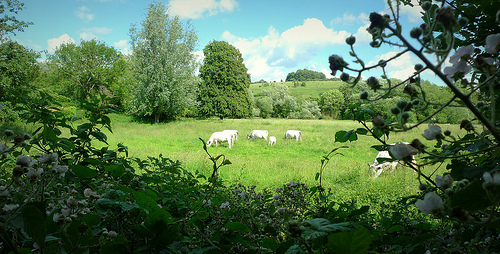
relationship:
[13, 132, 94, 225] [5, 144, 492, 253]
flowers in foreground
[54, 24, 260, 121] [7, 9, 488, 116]
trees in background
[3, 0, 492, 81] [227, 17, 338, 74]
sky has clouds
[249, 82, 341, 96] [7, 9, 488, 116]
meadow in background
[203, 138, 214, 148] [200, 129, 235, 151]
head of cow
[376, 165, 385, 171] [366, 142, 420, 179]
ear of cow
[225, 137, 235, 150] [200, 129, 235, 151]
legs of cow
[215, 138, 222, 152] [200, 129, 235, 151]
leg of cow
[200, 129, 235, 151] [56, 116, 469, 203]
cow on grass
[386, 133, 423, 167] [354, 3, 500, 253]
flower on plant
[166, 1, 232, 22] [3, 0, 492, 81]
cloud in sky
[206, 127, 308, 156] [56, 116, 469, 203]
sheep in field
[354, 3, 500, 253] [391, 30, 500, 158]
plant has flowers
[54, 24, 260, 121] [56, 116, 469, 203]
trees line field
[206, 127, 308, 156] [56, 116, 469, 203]
animals in field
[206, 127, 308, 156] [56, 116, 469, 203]
animals on field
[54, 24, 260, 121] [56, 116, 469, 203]
trees in field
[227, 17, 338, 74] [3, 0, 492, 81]
clouds in sky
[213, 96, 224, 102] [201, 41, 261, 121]
leaves on tree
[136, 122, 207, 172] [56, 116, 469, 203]
grass on field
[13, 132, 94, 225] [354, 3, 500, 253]
flowers on plant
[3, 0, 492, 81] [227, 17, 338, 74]
sky with clouds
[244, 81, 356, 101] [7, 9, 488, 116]
hills in background